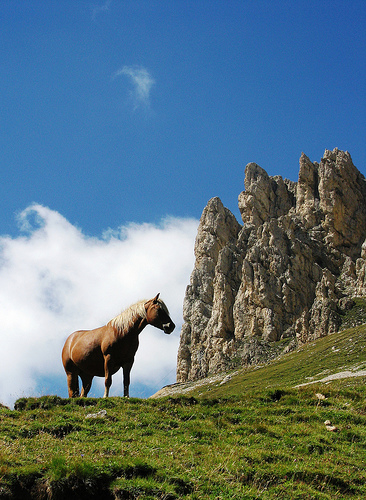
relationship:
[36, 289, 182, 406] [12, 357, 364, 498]
horse standing in field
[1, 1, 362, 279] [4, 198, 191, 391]
sky covered with clouds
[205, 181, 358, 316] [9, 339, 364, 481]
hill adjacent to field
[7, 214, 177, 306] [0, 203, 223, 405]
cloud in sky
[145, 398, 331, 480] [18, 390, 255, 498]
green grass on hill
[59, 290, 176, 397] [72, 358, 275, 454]
horse on hill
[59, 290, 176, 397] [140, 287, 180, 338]
horse has head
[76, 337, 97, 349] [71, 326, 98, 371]
coat on torso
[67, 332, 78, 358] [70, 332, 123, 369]
light on coat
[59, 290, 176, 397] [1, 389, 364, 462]
horse on field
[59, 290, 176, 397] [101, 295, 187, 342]
horse has blonde hair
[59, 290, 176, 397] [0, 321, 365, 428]
horse on green grass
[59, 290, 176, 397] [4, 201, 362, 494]
horse in valley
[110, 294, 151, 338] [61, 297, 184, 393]
blonde mane on horse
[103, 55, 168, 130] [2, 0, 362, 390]
cloud in sky